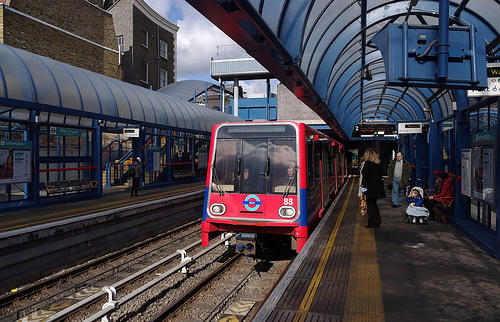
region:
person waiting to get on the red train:
[407, 188, 427, 222]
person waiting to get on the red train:
[386, 150, 411, 200]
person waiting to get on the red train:
[362, 153, 383, 226]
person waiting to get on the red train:
[355, 148, 369, 222]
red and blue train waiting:
[200, 119, 349, 256]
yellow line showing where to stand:
[300, 169, 357, 314]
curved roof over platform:
[195, 1, 498, 319]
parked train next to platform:
[200, 121, 352, 318]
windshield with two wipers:
[212, 139, 297, 199]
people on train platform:
[265, 146, 497, 320]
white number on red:
[282, 196, 294, 206]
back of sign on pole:
[377, 1, 484, 83]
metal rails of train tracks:
[0, 220, 282, 319]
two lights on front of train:
[211, 203, 296, 216]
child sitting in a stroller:
[404, 183, 429, 223]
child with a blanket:
[404, 184, 431, 226]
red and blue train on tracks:
[196, 113, 355, 261]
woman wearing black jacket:
[359, 144, 386, 231]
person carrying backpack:
[126, 155, 148, 194]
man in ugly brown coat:
[384, 150, 414, 206]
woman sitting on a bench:
[427, 168, 454, 228]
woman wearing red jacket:
[428, 168, 454, 220]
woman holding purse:
[354, 146, 386, 227]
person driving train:
[275, 166, 300, 193]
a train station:
[16, 12, 488, 314]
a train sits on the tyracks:
[188, 98, 358, 257]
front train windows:
[187, 117, 316, 214]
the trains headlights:
[208, 198, 302, 230]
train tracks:
[7, 225, 287, 319]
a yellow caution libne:
[289, 165, 359, 320]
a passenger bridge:
[191, 43, 293, 119]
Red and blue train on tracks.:
[183, 97, 352, 275]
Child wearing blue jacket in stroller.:
[395, 175, 432, 229]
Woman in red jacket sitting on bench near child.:
[407, 152, 462, 228]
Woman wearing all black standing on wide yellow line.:
[351, 143, 390, 239]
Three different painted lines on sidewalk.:
[281, 162, 379, 319]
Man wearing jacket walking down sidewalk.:
[374, 133, 421, 228]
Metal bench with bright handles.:
[27, 155, 114, 206]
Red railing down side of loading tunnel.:
[155, 150, 207, 189]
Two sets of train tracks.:
[1, 208, 262, 320]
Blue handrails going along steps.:
[95, 122, 157, 191]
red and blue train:
[201, 115, 352, 257]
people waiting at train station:
[345, 143, 455, 226]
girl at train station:
[127, 150, 143, 194]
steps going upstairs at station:
[104, 135, 127, 180]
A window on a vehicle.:
[233, 126, 277, 205]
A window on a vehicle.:
[206, 130, 246, 206]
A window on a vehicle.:
[269, 132, 304, 206]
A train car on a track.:
[204, 100, 325, 259]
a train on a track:
[189, 121, 351, 267]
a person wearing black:
[352, 145, 387, 232]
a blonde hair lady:
[356, 138, 389, 235]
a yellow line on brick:
[326, 202, 351, 320]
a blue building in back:
[1, 65, 188, 222]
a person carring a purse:
[121, 151, 152, 196]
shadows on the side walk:
[320, 225, 486, 320]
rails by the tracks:
[96, 240, 183, 315]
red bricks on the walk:
[323, 271, 340, 320]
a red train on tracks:
[166, 92, 379, 314]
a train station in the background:
[2, 32, 296, 317]